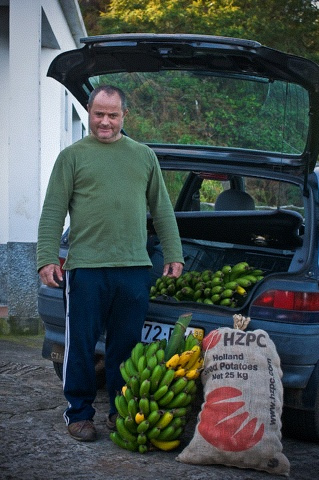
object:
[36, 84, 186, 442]
man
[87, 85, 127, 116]
hair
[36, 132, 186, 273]
shirt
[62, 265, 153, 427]
pants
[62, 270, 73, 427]
stripe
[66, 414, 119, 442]
shoes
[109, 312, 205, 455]
bananas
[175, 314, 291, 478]
sack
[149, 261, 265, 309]
bananas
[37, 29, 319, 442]
car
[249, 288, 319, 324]
tail lights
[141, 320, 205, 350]
license plate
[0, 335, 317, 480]
ground